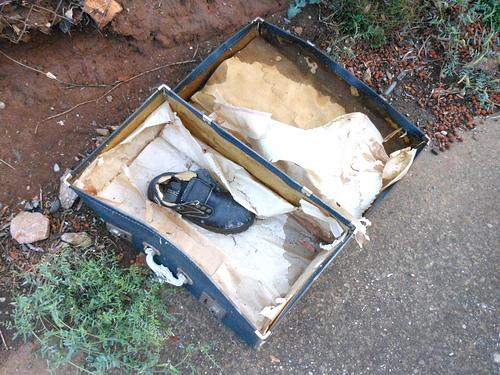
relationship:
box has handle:
[63, 14, 431, 350] [103, 231, 192, 300]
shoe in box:
[147, 168, 256, 235] [177, 12, 429, 182]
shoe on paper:
[147, 168, 256, 235] [71, 101, 346, 334]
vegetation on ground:
[19, 218, 216, 359] [0, 110, 306, 368]